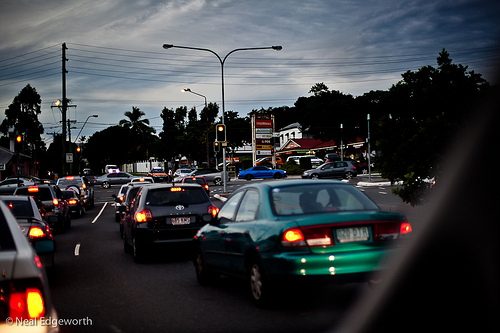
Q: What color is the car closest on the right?
A: Green.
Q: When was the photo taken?
A: Daytime.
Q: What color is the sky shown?
A: White and blue.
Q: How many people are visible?
A: One.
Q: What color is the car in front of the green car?
A: Black.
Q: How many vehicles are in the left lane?
A: Five.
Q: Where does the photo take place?
A: In the city.